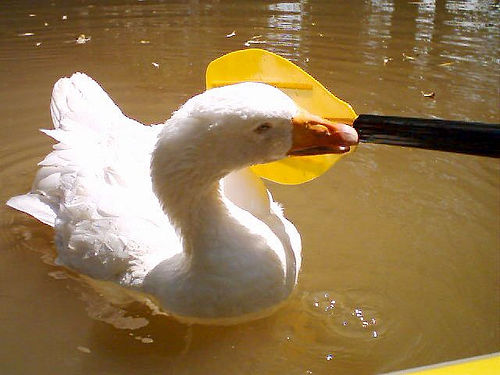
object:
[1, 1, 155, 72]
water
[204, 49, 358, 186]
plastic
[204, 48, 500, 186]
paddle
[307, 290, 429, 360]
ripple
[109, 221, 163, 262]
feathers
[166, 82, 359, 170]
head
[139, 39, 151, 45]
leaf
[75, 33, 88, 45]
leaf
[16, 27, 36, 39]
leaf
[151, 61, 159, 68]
leaf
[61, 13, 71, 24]
leaf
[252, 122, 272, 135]
eye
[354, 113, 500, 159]
pole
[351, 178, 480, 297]
murky water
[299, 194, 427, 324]
water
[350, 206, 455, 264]
water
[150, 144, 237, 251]
long neck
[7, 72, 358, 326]
swan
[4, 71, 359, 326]
duck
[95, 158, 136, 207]
feathers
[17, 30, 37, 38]
leaves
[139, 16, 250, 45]
water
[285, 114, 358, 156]
beak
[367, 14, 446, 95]
water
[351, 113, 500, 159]
stick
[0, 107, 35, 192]
water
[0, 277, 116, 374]
water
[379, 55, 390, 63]
leaf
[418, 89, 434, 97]
leaf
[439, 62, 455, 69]
leaf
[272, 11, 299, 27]
light